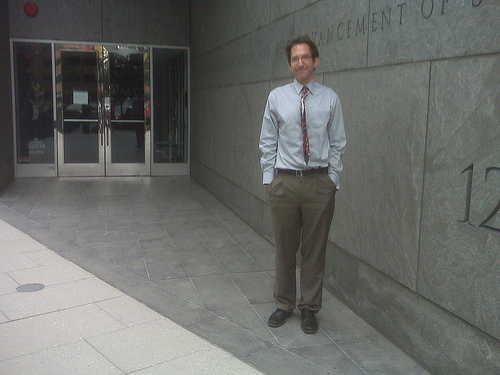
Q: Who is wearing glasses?
A: The man.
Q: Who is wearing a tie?
A: The man.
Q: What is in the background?
A: The front door.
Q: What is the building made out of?
A: Granite.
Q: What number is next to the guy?
A: 12.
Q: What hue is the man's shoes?
A: Black.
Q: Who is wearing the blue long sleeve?
A: The man.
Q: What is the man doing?
A: Smiling.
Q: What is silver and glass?
A: The door.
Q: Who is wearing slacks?
A: The man.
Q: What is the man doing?
A: Standing at an office.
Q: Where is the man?
A: Front of building.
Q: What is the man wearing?
A: Blue shirt.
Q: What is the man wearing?
A: Tie.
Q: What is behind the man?
A: Glass door.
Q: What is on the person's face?
A: Glasses.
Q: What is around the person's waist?
A: Belt.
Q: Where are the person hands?
A: In pocket.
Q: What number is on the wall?
A: 12.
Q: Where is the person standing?
A: Outside a building.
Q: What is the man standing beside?
A: A wall.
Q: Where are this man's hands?
A: In his pockets.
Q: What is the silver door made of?
A: Metal.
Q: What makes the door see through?
A: Glass.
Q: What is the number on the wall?
A: 12.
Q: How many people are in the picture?
A: One.